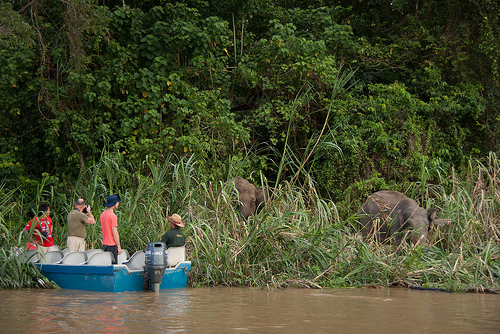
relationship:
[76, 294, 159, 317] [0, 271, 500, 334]
reflection in river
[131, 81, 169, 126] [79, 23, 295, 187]
leaves on tree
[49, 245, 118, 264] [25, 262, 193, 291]
seats on boat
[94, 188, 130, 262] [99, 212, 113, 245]
man wearing shirt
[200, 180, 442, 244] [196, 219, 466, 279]
elephants eating grass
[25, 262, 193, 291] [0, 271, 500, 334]
boat in river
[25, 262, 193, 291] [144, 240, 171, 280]
boat has motor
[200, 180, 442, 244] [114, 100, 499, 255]
elephants in bushes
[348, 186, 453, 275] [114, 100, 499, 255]
elephant laying in bushes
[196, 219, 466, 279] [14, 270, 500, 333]
grass on side of river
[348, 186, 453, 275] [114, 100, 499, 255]
elephant in bushes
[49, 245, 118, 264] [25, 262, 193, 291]
seats inside boat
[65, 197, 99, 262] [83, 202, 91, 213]
man has camera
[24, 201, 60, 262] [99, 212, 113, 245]
people wearing shirt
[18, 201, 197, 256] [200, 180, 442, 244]
people looking at elephants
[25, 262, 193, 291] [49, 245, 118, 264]
boat has seats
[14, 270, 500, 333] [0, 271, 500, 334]
river has river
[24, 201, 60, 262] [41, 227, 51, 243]
people wearing camera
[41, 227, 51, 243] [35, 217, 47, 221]
camera around neck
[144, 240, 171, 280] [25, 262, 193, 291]
motor on back f boat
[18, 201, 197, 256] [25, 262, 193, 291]
people on boat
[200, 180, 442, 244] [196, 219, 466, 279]
elephants in grass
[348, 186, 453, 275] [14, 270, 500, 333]
elephant standing by river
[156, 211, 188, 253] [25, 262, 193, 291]
man sitting on boat